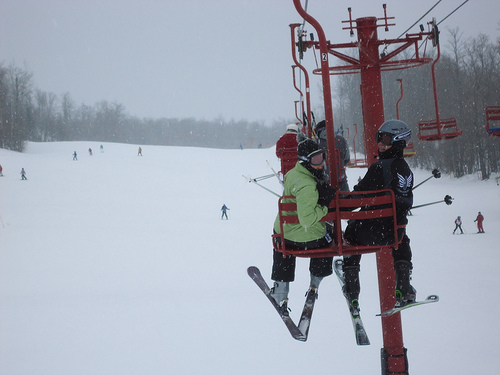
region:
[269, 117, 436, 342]
TWO PEOPLE ON A SKI LIFT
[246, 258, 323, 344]
A PAIR OF SKIS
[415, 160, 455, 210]
A PAIR OF SKI POLES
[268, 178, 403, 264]
A RED METAL SKI LIFT CHAIR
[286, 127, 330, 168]
A BLACK AND WHIT HAT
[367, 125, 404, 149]
A PAIR OF SKI GOGGLES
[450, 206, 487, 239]
TWO PEOPLE ON THE SNOW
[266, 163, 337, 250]
A GREEN SKI JACKET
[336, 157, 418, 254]
A BLACK SKI JACKET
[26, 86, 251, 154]
TREES IN THE DISTANCE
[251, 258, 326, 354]
two skis and boots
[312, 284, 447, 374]
green and gary skis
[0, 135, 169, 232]
group of people skiing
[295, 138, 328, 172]
black ski goggles and hat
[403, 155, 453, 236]
silver and black ski poles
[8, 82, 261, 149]
trees and snow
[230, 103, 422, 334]
two people on a ski lift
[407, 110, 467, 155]
empty resd ski lift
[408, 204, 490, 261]
two people skiing together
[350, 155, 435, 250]
wings on a jacket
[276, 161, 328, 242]
green jacket on skier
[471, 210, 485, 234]
skier wearing red suit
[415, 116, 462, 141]
empty red ski lift chair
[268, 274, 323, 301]
white ski boots on skier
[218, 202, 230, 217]
skier wearing blue ski suit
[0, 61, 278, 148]
trees with no leaves in the background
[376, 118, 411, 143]
grey helmet on skier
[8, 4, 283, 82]
cloudy snowing sky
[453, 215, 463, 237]
red and white jacket on skier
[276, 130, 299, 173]
red jacket on skier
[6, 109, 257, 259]
People are skiing in the distance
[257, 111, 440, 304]
The people are on the lift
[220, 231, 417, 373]
The people have skis on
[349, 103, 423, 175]
The man has goggles on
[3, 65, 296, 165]
The trees are in the distance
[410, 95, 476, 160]
The lift is empty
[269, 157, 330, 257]
The person has a green jacket on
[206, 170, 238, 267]
The person is going down the hill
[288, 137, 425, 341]
The lift machine is red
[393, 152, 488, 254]
The man is holding the poles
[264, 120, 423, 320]
People riding a ski lift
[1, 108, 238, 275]
People skiing downhill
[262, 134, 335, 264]
A woman in a green jacket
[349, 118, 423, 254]
A person in a black jacket on the ski lift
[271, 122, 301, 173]
A person in a white hat and red jacket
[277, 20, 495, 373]
A red metal ski lift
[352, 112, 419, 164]
A grey helmet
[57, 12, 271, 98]
A grey sky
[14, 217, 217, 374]
Snow covered ground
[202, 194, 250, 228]
A person in blue skiing